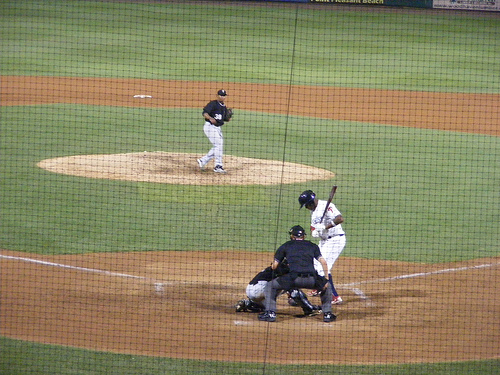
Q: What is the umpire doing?
A: Making the call.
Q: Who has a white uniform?
A: The batter.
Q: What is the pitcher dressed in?
A: White and black.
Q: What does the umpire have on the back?
A: Black shirt.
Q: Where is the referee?
A: At home plate.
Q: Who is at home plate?
A: The batter with the bat.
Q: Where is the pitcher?
A: The center of the baseball field.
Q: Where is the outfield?
A: In the field.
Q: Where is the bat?
A: In the batter's hand.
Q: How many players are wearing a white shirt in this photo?
A: One.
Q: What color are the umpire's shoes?
A: Black.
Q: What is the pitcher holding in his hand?
A: A glove.